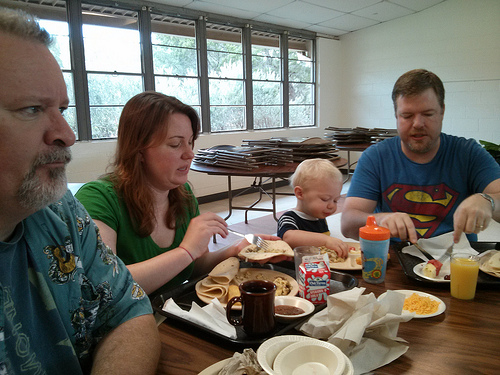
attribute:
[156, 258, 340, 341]
tray — plastic, black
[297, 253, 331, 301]
milk carton — red, white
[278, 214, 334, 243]
boy's shirt — striped, black, white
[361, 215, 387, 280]
sippy cup — blue, orange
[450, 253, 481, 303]
cup — plastic, orange, clear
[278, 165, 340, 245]
baby — blond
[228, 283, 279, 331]
coffee mug — dark brown, brown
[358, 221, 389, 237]
sippy cup lid — orange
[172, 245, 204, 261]
bracelet — red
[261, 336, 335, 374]
plate — white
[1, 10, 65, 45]
mans hair — gray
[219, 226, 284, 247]
fork — silver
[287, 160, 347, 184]
boys hair — blonde